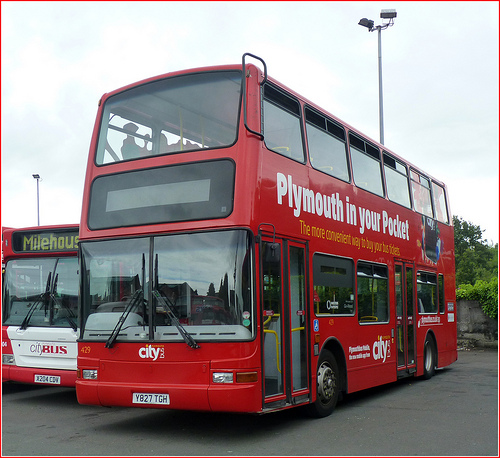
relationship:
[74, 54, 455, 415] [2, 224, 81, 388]
bus next to bus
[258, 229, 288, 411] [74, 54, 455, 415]
door on bus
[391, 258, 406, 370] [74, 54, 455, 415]
door on bus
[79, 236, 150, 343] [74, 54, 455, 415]
windshield on bus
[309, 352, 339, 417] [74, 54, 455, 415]
wheel on bus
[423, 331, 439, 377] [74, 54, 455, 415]
wheel on bus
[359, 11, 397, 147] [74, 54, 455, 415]
pole behind bus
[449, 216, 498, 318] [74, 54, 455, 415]
tree behind bus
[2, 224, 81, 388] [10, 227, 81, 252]
bus has sign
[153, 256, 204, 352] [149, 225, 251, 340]
wiper on windshield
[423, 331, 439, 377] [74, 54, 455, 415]
tire on bus